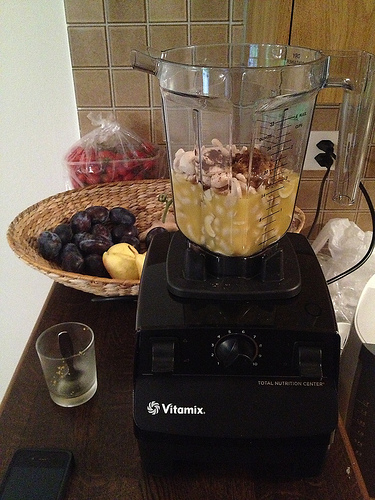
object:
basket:
[8, 178, 306, 295]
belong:
[132, 425, 336, 484]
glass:
[35, 317, 99, 409]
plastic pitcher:
[130, 40, 372, 260]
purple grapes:
[37, 229, 63, 262]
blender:
[126, 142, 374, 474]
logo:
[144, 399, 210, 419]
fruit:
[102, 241, 142, 278]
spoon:
[56, 330, 84, 381]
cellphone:
[6, 449, 70, 497]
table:
[0, 283, 372, 499]